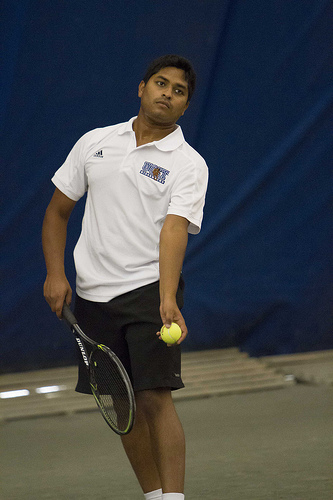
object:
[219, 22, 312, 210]
blue backdrop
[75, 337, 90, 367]
brand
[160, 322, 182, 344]
ball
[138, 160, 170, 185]
logo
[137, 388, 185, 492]
leg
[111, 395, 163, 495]
leg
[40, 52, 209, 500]
man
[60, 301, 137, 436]
racquet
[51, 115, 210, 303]
shirt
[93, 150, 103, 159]
logo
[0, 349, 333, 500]
tennis court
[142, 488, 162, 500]
sock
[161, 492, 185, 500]
sock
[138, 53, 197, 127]
head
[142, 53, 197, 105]
hair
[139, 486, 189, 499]
beach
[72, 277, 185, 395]
shorts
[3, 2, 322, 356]
backdrop